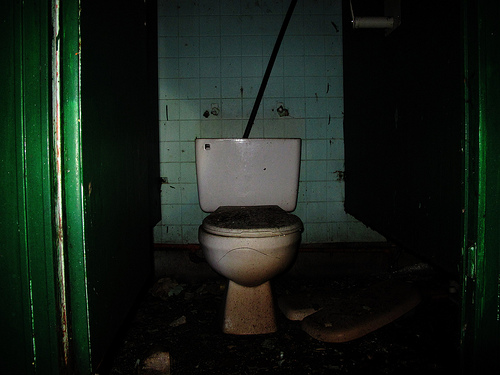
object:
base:
[224, 280, 275, 337]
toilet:
[193, 133, 303, 336]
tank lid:
[195, 136, 301, 216]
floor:
[107, 265, 496, 372]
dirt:
[213, 339, 239, 353]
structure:
[337, 0, 471, 282]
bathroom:
[0, 0, 497, 372]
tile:
[221, 99, 241, 120]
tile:
[220, 35, 242, 57]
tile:
[241, 77, 264, 98]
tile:
[283, 77, 303, 96]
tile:
[242, 118, 265, 136]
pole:
[243, 2, 298, 142]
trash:
[253, 338, 291, 369]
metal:
[52, 1, 72, 370]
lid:
[302, 272, 420, 345]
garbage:
[147, 273, 188, 305]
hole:
[360, 0, 390, 15]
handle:
[341, 0, 402, 37]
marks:
[328, 166, 346, 182]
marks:
[196, 103, 222, 124]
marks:
[273, 101, 294, 124]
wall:
[157, 2, 342, 244]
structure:
[0, 1, 162, 367]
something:
[219, 209, 287, 223]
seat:
[203, 208, 303, 233]